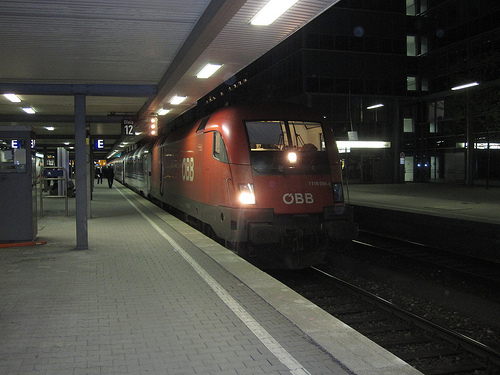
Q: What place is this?
A: It is a station.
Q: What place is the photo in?
A: It is at the station.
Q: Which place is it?
A: It is a station.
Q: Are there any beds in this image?
A: No, there are no beds.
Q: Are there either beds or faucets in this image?
A: No, there are no beds or faucets.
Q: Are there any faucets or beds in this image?
A: No, there are no beds or faucets.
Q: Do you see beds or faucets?
A: No, there are no beds or faucets.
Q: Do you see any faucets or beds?
A: No, there are no beds or faucets.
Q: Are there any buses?
A: No, there are no buses.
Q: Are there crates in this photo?
A: No, there are no crates.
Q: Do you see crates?
A: No, there are no crates.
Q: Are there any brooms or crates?
A: No, there are no crates or brooms.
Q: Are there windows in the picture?
A: Yes, there are windows.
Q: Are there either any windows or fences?
A: Yes, there are windows.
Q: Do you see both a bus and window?
A: No, there are windows but no buses.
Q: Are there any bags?
A: No, there are no bags.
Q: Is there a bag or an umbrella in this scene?
A: No, there are no bags or umbrellas.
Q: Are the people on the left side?
A: Yes, the people are on the left of the image.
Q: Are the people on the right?
A: No, the people are on the left of the image.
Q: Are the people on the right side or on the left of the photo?
A: The people are on the left of the image.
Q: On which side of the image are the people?
A: The people are on the left of the image.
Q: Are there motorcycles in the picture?
A: No, there are no motorcycles.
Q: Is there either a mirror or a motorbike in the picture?
A: No, there are no motorcycles or mirrors.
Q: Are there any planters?
A: No, there are no planters.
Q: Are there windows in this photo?
A: Yes, there is a window.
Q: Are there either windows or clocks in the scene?
A: Yes, there is a window.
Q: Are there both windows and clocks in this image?
A: No, there is a window but no clocks.